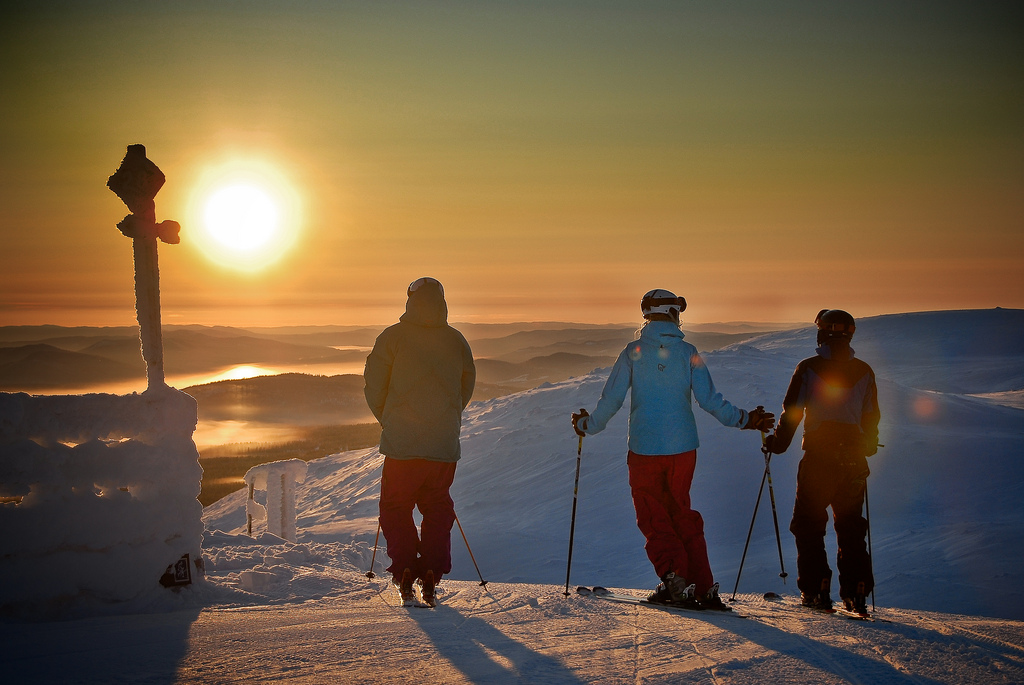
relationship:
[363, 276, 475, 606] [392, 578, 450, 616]
person standing on skis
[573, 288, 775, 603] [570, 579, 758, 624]
person standing on skis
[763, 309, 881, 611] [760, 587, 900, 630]
person standing on skis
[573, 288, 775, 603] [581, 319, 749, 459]
person wearing a coat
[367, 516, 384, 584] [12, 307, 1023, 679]
ski pole stuck in snow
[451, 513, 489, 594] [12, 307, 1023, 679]
ski pole stuck in snow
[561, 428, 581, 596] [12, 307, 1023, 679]
ski pole stuck in snow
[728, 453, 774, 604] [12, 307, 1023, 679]
ski pole stuck in snow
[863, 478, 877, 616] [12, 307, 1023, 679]
ski pole stuck in snow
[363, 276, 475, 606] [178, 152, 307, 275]
person watching sun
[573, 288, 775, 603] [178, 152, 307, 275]
person watching sun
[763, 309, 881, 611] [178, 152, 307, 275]
person watching sun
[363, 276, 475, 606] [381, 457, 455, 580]
person wearing pants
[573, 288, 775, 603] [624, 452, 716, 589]
person wearing pants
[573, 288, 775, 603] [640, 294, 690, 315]
person wearing goggles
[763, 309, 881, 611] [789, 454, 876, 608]
person wearing pants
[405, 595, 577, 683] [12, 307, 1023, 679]
shadow on snow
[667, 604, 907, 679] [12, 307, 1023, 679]
shadow on snow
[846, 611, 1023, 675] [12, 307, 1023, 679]
shadow on snow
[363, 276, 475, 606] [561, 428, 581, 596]
person holding ski pole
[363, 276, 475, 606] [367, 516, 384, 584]
person holding ski pole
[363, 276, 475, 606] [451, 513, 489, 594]
person holding ski pole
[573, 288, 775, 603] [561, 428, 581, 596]
person holding ski pole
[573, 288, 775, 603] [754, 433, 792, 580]
person holding ski pole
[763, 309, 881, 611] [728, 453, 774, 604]
person holding ski pole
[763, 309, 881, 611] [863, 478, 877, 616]
person holding ski pole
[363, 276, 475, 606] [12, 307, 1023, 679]
person standing on snow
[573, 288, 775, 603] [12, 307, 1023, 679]
person standing on snow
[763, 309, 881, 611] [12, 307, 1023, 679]
person standing on snow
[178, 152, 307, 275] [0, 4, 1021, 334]
sun in sky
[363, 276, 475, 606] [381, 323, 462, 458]
person has a back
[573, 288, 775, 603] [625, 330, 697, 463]
person has a back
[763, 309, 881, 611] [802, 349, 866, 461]
person has a back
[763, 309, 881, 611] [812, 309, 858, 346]
person wearing a helmet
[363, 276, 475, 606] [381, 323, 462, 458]
person has back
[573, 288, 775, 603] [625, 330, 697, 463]
person has back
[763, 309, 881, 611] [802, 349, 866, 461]
person has back